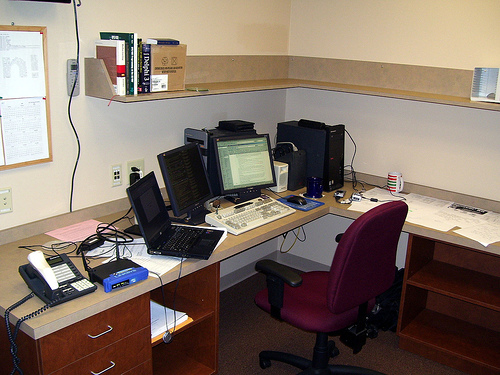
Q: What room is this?
A: It is an office.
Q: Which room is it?
A: It is an office.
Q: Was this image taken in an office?
A: Yes, it was taken in an office.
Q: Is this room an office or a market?
A: It is an office.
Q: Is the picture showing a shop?
A: No, the picture is showing an office.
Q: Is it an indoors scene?
A: Yes, it is indoors.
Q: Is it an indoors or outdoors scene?
A: It is indoors.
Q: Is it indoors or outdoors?
A: It is indoors.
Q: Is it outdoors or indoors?
A: It is indoors.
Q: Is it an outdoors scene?
A: No, it is indoors.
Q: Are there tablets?
A: No, there are no tablets.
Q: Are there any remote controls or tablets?
A: No, there are no tablets or remote controls.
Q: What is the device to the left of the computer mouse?
A: The device is a computer monitor.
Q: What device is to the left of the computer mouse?
A: The device is a computer monitor.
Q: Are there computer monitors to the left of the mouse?
A: Yes, there is a computer monitor to the left of the mouse.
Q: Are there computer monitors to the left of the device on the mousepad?
A: Yes, there is a computer monitor to the left of the mouse.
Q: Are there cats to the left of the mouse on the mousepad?
A: No, there is a computer monitor to the left of the computer mouse.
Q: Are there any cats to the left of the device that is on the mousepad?
A: No, there is a computer monitor to the left of the computer mouse.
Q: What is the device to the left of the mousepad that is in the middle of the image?
A: The device is a computer monitor.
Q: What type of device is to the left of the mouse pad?
A: The device is a computer monitor.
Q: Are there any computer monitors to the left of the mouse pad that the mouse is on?
A: Yes, there is a computer monitor to the left of the mousepad.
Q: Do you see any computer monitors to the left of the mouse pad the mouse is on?
A: Yes, there is a computer monitor to the left of the mousepad.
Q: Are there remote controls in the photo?
A: No, there are no remote controls.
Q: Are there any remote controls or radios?
A: No, there are no remote controls or radios.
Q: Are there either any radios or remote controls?
A: No, there are no remote controls or radios.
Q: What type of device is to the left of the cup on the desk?
A: The device is a computer monitor.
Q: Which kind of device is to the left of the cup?
A: The device is a computer monitor.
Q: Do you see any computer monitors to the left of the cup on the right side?
A: Yes, there is a computer monitor to the left of the cup.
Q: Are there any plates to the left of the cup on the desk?
A: No, there is a computer monitor to the left of the cup.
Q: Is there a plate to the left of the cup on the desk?
A: No, there is a computer monitor to the left of the cup.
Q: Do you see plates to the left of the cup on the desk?
A: No, there is a computer monitor to the left of the cup.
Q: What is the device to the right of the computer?
A: The device is a computer monitor.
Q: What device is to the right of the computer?
A: The device is a computer monitor.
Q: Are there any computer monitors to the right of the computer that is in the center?
A: Yes, there is a computer monitor to the right of the computer.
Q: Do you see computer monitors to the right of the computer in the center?
A: Yes, there is a computer monitor to the right of the computer.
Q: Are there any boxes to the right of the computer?
A: No, there is a computer monitor to the right of the computer.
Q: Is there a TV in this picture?
A: No, there are no televisions.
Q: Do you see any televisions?
A: No, there are no televisions.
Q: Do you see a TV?
A: No, there are no televisions.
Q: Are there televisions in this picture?
A: No, there are no televisions.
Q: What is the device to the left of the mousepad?
A: The device is a computer monitor.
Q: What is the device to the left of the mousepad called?
A: The device is a computer monitor.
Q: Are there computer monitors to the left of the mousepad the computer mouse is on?
A: Yes, there is a computer monitor to the left of the mousepad.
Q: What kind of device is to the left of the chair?
A: The device is a computer monitor.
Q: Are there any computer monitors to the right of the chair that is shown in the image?
A: No, the computer monitor is to the left of the chair.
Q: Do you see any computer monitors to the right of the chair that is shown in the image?
A: No, the computer monitor is to the left of the chair.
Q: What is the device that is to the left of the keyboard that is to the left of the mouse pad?
A: The device is a computer monitor.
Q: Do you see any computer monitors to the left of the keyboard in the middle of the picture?
A: Yes, there is a computer monitor to the left of the keyboard.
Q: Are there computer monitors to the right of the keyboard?
A: No, the computer monitor is to the left of the keyboard.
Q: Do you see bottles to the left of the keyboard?
A: No, there is a computer monitor to the left of the keyboard.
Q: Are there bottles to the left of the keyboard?
A: No, there is a computer monitor to the left of the keyboard.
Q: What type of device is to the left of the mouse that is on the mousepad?
A: The device is a computer monitor.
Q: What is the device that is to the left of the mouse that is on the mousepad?
A: The device is a computer monitor.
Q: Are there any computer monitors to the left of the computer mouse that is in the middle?
A: Yes, there is a computer monitor to the left of the computer mouse.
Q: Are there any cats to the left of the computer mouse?
A: No, there is a computer monitor to the left of the computer mouse.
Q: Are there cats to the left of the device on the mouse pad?
A: No, there is a computer monitor to the left of the computer mouse.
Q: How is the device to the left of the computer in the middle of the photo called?
A: The device is a computer monitor.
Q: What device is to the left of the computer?
A: The device is a computer monitor.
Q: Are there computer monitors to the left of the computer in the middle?
A: Yes, there is a computer monitor to the left of the computer.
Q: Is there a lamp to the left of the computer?
A: No, there is a computer monitor to the left of the computer.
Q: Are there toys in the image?
A: No, there are no toys.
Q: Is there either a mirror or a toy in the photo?
A: No, there are no toys or mirrors.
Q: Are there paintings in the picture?
A: No, there are no paintings.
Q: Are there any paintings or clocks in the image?
A: No, there are no paintings or clocks.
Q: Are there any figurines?
A: No, there are no figurines.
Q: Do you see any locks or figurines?
A: No, there are no figurines or locks.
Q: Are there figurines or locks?
A: No, there are no figurines or locks.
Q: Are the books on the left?
A: Yes, the books are on the left of the image.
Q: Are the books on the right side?
A: No, the books are on the left of the image.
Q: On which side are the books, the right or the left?
A: The books are on the left of the image.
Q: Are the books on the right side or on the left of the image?
A: The books are on the left of the image.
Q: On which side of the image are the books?
A: The books are on the left of the image.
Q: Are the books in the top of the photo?
A: Yes, the books are in the top of the image.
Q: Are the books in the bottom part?
A: No, the books are in the top of the image.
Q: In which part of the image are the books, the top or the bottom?
A: The books are in the top of the image.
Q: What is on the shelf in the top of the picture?
A: The books are on the shelf.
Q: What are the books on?
A: The books are on the shelf.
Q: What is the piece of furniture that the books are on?
A: The piece of furniture is a shelf.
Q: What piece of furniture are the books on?
A: The books are on the shelf.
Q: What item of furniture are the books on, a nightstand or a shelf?
A: The books are on a shelf.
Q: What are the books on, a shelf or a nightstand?
A: The books are on a shelf.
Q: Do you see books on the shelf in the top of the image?
A: Yes, there are books on the shelf.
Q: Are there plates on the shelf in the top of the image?
A: No, there are books on the shelf.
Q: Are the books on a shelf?
A: Yes, the books are on a shelf.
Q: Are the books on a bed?
A: No, the books are on a shelf.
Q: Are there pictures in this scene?
A: No, there are no pictures.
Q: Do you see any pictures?
A: No, there are no pictures.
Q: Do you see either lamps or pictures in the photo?
A: No, there are no pictures or lamps.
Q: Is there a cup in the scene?
A: Yes, there is a cup.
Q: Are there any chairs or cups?
A: Yes, there is a cup.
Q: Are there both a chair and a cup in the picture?
A: Yes, there are both a cup and a chair.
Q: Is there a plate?
A: No, there are no plates.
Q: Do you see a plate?
A: No, there are no plates.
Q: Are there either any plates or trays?
A: No, there are no plates or trays.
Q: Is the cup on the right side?
A: Yes, the cup is on the right of the image.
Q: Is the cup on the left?
A: No, the cup is on the right of the image.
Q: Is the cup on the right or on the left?
A: The cup is on the right of the image.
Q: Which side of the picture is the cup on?
A: The cup is on the right of the image.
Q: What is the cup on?
A: The cup is on the desk.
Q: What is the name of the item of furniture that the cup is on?
A: The piece of furniture is a desk.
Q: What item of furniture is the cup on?
A: The cup is on the desk.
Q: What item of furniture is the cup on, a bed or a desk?
A: The cup is on a desk.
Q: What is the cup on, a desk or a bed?
A: The cup is on a desk.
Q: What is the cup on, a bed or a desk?
A: The cup is on a desk.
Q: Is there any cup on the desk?
A: Yes, there is a cup on the desk.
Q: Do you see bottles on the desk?
A: No, there is a cup on the desk.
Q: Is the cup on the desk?
A: Yes, the cup is on the desk.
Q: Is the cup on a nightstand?
A: No, the cup is on the desk.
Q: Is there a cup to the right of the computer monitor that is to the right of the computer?
A: Yes, there is a cup to the right of the computer monitor.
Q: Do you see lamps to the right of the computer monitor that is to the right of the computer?
A: No, there is a cup to the right of the computer monitor.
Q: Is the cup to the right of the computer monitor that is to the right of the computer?
A: Yes, the cup is to the right of the computer monitor.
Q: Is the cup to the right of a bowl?
A: No, the cup is to the right of the computer monitor.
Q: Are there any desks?
A: Yes, there is a desk.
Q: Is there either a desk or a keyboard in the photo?
A: Yes, there is a desk.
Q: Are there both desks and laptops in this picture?
A: Yes, there are both a desk and a laptop.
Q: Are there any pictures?
A: No, there are no pictures.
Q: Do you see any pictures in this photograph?
A: No, there are no pictures.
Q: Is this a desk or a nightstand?
A: This is a desk.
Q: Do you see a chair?
A: Yes, there is a chair.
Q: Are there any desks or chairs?
A: Yes, there is a chair.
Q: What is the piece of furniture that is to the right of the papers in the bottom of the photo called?
A: The piece of furniture is a chair.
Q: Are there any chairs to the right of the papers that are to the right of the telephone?
A: Yes, there is a chair to the right of the papers.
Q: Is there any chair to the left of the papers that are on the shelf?
A: No, the chair is to the right of the papers.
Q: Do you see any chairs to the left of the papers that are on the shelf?
A: No, the chair is to the right of the papers.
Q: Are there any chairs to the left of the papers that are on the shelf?
A: No, the chair is to the right of the papers.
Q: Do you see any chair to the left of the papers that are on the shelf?
A: No, the chair is to the right of the papers.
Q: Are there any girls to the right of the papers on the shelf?
A: No, there is a chair to the right of the papers.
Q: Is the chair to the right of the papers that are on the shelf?
A: Yes, the chair is to the right of the papers.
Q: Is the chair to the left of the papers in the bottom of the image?
A: No, the chair is to the right of the papers.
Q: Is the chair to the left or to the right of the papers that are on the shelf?
A: The chair is to the right of the papers.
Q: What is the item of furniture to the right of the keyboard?
A: The piece of furniture is a chair.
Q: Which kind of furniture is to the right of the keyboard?
A: The piece of furniture is a chair.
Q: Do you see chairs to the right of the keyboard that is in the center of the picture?
A: Yes, there is a chair to the right of the keyboard.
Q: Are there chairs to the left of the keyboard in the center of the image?
A: No, the chair is to the right of the keyboard.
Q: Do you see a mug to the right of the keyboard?
A: No, there is a chair to the right of the keyboard.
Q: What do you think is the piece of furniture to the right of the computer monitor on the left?
A: The piece of furniture is a chair.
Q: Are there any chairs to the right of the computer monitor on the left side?
A: Yes, there is a chair to the right of the computer monitor.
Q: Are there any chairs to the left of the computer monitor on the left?
A: No, the chair is to the right of the computer monitor.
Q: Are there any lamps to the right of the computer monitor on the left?
A: No, there is a chair to the right of the computer monitor.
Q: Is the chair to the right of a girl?
A: No, the chair is to the right of the computer monitor.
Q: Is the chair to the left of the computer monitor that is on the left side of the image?
A: No, the chair is to the right of the computer monitor.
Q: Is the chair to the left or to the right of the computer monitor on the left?
A: The chair is to the right of the computer monitor.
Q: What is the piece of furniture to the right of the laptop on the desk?
A: The piece of furniture is a chair.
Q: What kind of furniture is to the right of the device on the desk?
A: The piece of furniture is a chair.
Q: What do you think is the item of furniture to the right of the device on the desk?
A: The piece of furniture is a chair.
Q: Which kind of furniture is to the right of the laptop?
A: The piece of furniture is a chair.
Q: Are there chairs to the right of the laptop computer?
A: Yes, there is a chair to the right of the laptop computer.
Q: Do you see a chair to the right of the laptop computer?
A: Yes, there is a chair to the right of the laptop computer.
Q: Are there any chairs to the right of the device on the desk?
A: Yes, there is a chair to the right of the laptop computer.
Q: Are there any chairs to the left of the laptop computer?
A: No, the chair is to the right of the laptop computer.